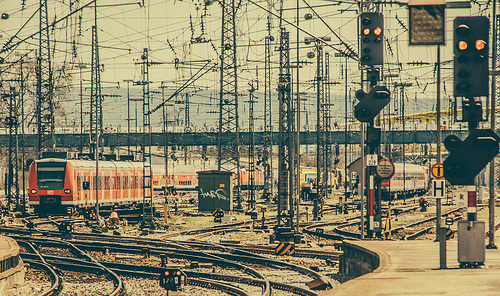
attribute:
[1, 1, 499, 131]
sky — cloudy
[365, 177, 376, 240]
pole — red, white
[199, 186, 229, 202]
graffiti — white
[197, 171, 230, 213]
building — green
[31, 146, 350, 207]
train — orange, black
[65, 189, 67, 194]
light — yellow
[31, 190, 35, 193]
light — yellow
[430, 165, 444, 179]
sign — yellow, round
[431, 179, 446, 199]
sign — white, square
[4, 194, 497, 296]
tracks — tangled, mess